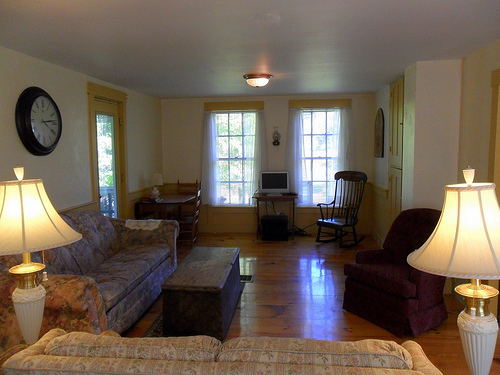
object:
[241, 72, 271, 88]
light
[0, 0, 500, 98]
ceiling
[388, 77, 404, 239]
door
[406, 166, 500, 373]
lamp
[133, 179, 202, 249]
table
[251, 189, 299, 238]
table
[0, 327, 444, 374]
couch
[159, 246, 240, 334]
table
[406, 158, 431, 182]
ground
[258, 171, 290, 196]
monitor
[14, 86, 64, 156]
clock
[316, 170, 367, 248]
chairs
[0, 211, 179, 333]
couch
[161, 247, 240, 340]
coffe table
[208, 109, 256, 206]
window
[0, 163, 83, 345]
lamp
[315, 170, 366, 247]
rocking chair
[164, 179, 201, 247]
chairs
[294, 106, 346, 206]
window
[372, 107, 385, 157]
wall art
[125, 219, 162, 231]
cloth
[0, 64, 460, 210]
wall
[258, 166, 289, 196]
television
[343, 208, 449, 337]
corner